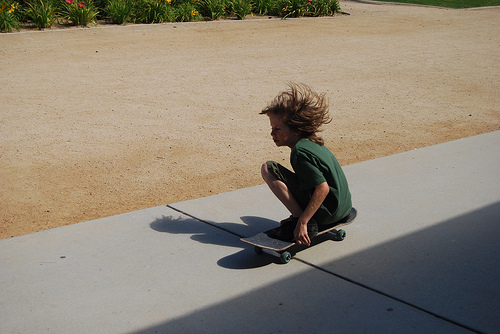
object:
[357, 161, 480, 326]
sidewalk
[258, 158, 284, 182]
knee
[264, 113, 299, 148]
face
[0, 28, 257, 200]
dirt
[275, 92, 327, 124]
boy's hair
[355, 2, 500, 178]
air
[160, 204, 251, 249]
boy's shadow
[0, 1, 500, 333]
photo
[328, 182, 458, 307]
pavement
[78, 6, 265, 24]
greenery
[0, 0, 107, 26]
flowers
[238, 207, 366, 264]
skateboard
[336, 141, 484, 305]
concrete slab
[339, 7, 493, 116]
dirt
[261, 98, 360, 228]
boy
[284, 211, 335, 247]
shoes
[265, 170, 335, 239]
shorts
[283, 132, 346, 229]
shirt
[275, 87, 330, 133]
hair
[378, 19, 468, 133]
wind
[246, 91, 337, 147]
head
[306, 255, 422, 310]
line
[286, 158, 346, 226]
elbow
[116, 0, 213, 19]
plant